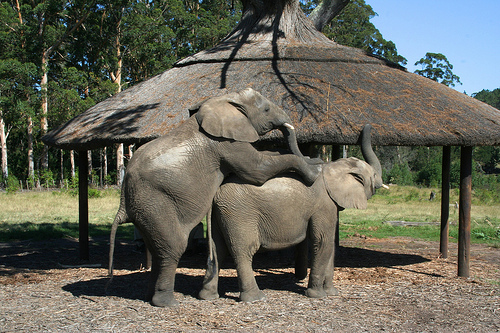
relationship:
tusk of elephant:
[284, 121, 298, 134] [199, 122, 385, 302]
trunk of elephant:
[357, 125, 382, 179] [199, 122, 385, 302]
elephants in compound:
[101, 86, 378, 310] [2, 179, 495, 329]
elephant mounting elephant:
[65, 67, 386, 304] [199, 122, 385, 302]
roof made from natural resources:
[54, 12, 495, 145] [380, 82, 442, 120]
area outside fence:
[2, 0, 488, 187] [1, 173, 498, 202]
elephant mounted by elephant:
[198, 122, 389, 302] [108, 84, 309, 301]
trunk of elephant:
[359, 121, 383, 186] [199, 122, 385, 302]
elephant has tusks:
[107, 86, 325, 308] [271, 110, 297, 137]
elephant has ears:
[106, 88, 323, 307] [186, 98, 257, 145]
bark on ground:
[7, 266, 494, 331] [5, 191, 496, 331]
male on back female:
[106, 77, 311, 307] [197, 120, 391, 302]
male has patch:
[106, 77, 311, 307] [145, 130, 212, 170]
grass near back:
[3, 189, 499, 208] [0, 182, 498, 211]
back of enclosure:
[0, 182, 498, 211] [0, 180, 500, 331]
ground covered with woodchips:
[1, 174, 497, 330] [0, 237, 497, 329]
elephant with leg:
[106, 88, 323, 307] [223, 142, 322, 186]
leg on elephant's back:
[223, 142, 322, 186] [218, 167, 321, 198]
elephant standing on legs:
[106, 88, 323, 307] [139, 233, 193, 310]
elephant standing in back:
[106, 88, 323, 307] [220, 176, 306, 212]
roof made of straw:
[41, 0, 500, 149] [282, 2, 312, 47]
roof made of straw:
[41, 0, 500, 149] [245, 11, 277, 46]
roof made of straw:
[41, 0, 500, 149] [217, 10, 255, 41]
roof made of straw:
[41, 0, 500, 149] [42, 40, 496, 148]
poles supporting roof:
[63, 136, 477, 303] [41, 0, 500, 149]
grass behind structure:
[3, 189, 500, 245] [63, 9, 486, 179]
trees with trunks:
[1, 4, 146, 195] [1, 51, 132, 195]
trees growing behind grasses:
[1, 4, 146, 195] [0, 179, 137, 263]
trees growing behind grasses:
[1, 4, 146, 195] [342, 181, 497, 251]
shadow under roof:
[0, 221, 445, 302] [42, 0, 499, 147]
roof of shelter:
[41, 0, 500, 149] [41, 0, 498, 277]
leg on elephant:
[223, 132, 328, 193] [107, 86, 325, 308]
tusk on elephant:
[378, 178, 396, 190] [61, 49, 308, 314]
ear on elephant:
[195, 95, 261, 142] [107, 86, 325, 308]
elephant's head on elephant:
[322, 138, 396, 205] [194, 120, 397, 307]